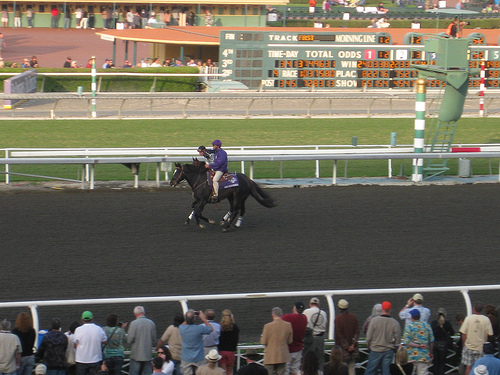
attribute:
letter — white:
[283, 30, 292, 42]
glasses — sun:
[156, 349, 168, 355]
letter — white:
[313, 48, 333, 58]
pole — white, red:
[476, 52, 487, 122]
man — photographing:
[190, 116, 238, 193]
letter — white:
[304, 47, 315, 58]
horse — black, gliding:
[167, 160, 279, 232]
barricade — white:
[0, 283, 500, 341]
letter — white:
[302, 45, 311, 60]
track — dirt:
[20, 193, 477, 281]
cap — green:
[76, 309, 94, 323]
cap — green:
[380, 300, 394, 313]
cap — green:
[409, 290, 425, 300]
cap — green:
[308, 296, 320, 305]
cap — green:
[213, 137, 223, 145]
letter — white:
[300, 44, 318, 61]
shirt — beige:
[196, 365, 224, 374]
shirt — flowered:
[398, 316, 435, 365]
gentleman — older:
[257, 297, 302, 373]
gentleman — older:
[199, 133, 226, 203]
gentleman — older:
[358, 288, 404, 373]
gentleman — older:
[449, 297, 489, 373]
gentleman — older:
[64, 301, 111, 371]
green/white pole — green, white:
[410, 89, 426, 187]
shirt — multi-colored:
[378, 319, 456, 370]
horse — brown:
[158, 151, 287, 235]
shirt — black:
[218, 325, 237, 350]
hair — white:
[132, 301, 147, 318]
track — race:
[3, 180, 482, 292]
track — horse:
[1, 155, 481, 286]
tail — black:
[238, 171, 281, 215]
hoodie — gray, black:
[193, 145, 218, 163]